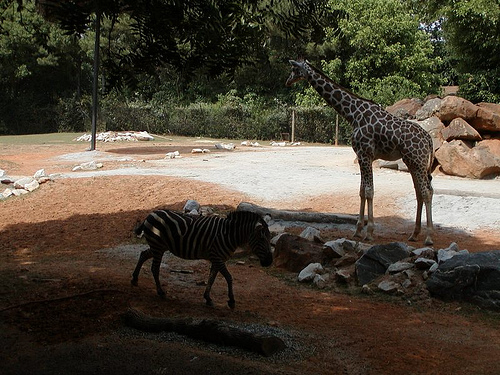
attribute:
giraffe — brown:
[288, 48, 468, 255]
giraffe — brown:
[262, 46, 443, 270]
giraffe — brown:
[259, 32, 439, 286]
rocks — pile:
[353, 72, 483, 199]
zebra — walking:
[119, 194, 320, 331]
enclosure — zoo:
[2, 4, 480, 365]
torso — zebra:
[166, 215, 234, 261]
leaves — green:
[1, 5, 480, 101]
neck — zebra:
[216, 212, 254, 265]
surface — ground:
[52, 263, 483, 373]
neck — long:
[310, 68, 376, 127]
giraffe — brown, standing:
[271, 40, 449, 258]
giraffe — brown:
[270, 48, 461, 270]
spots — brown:
[312, 69, 328, 92]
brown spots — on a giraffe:
[374, 109, 399, 148]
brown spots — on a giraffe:
[336, 94, 363, 115]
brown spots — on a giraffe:
[410, 143, 424, 158]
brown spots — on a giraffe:
[355, 109, 374, 128]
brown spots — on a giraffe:
[416, 167, 425, 192]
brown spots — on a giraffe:
[356, 140, 375, 159]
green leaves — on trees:
[3, 1, 389, 125]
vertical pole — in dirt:
[88, 3, 104, 156]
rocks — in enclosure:
[413, 100, 484, 180]